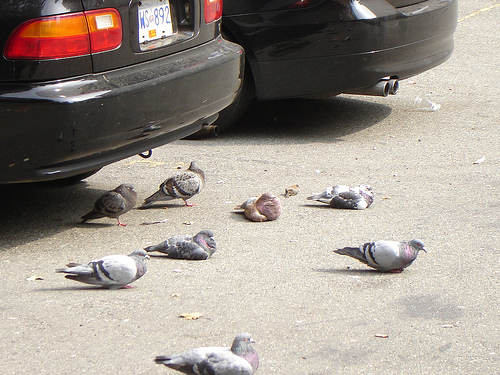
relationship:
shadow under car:
[173, 95, 394, 149] [179, 0, 460, 140]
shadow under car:
[0, 180, 114, 254] [1, 1, 245, 188]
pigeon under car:
[76, 180, 139, 233] [1, 1, 245, 188]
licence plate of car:
[136, 0, 174, 46] [1, 1, 245, 188]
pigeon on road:
[302, 182, 376, 213] [2, 1, 500, 373]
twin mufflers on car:
[340, 76, 401, 98] [179, 0, 460, 140]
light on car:
[203, 0, 223, 24] [1, 1, 245, 188]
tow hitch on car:
[136, 148, 155, 160] [1, 1, 245, 188]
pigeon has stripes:
[54, 244, 153, 292] [92, 260, 115, 283]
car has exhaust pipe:
[1, 1, 245, 188] [180, 124, 220, 140]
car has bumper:
[179, 0, 460, 140] [225, 1, 457, 102]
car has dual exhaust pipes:
[179, 0, 460, 140] [340, 74, 401, 97]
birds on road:
[56, 158, 430, 373] [2, 1, 500, 373]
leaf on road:
[284, 182, 303, 201] [2, 1, 500, 373]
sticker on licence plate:
[147, 29, 159, 37] [136, 0, 174, 46]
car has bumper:
[1, 1, 245, 188] [1, 32, 246, 182]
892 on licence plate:
[153, 6, 170, 27] [136, 0, 174, 46]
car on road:
[179, 0, 460, 140] [2, 1, 500, 373]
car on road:
[1, 1, 245, 188] [2, 1, 500, 373]